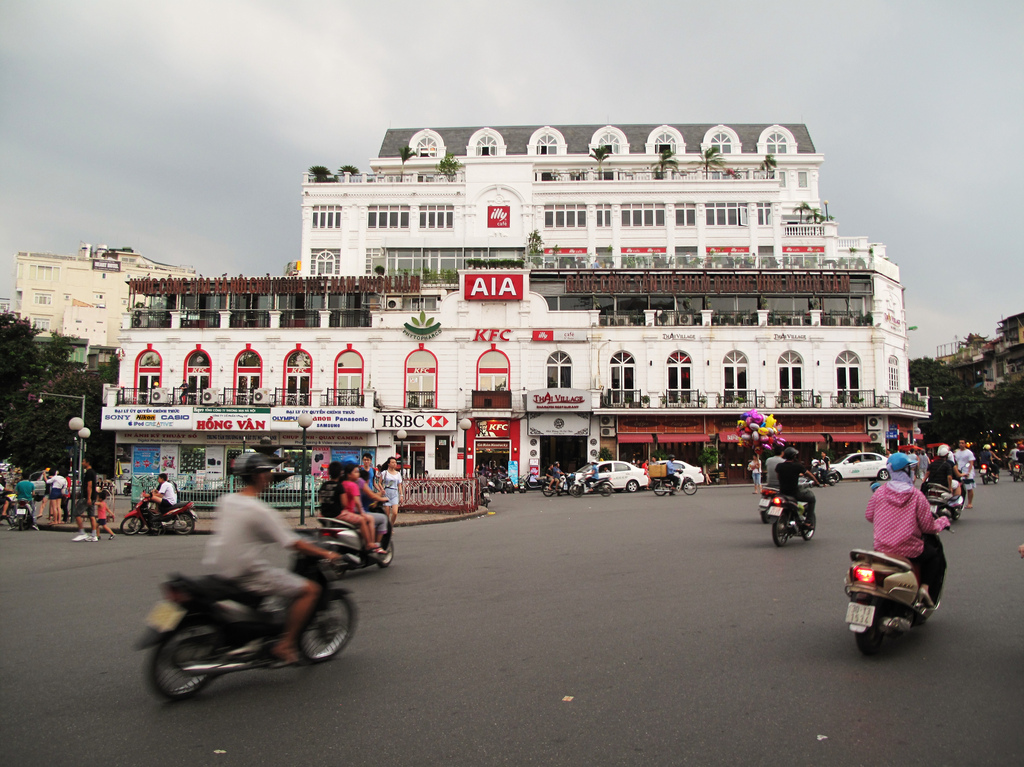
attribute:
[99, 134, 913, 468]
building — white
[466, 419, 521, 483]
doorway — red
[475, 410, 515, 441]
sign — KFC, red